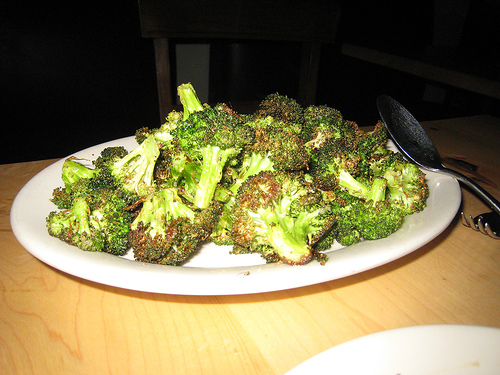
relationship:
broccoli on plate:
[46, 81, 431, 267] [7, 126, 465, 300]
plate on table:
[7, 126, 465, 300] [2, 107, 499, 375]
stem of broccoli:
[175, 81, 206, 120] [46, 81, 431, 267]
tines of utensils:
[460, 212, 497, 243] [375, 91, 500, 216]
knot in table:
[444, 152, 497, 187] [2, 107, 499, 375]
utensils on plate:
[375, 91, 500, 216] [7, 126, 465, 300]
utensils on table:
[457, 208, 500, 241] [2, 107, 499, 375]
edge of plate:
[96, 255, 299, 307] [7, 126, 465, 300]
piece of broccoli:
[131, 189, 224, 267] [46, 81, 431, 267]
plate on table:
[276, 322, 499, 374] [2, 107, 499, 375]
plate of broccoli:
[7, 126, 465, 300] [46, 81, 431, 267]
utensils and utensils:
[375, 91, 500, 216] [457, 208, 500, 241]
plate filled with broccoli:
[7, 126, 465, 300] [46, 81, 431, 267]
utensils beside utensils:
[375, 91, 500, 216] [457, 208, 500, 241]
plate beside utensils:
[7, 126, 465, 300] [457, 208, 500, 241]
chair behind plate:
[136, 1, 341, 131] [7, 126, 465, 300]